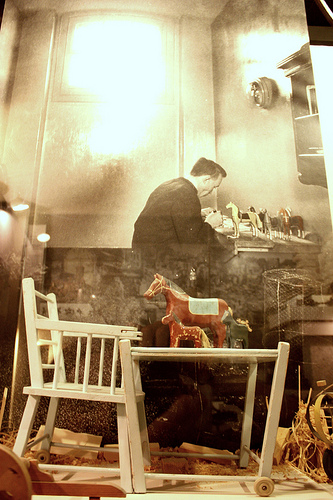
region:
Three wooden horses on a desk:
[143, 272, 249, 348]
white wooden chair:
[12, 278, 150, 493]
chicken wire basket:
[260, 268, 331, 363]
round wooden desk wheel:
[252, 476, 274, 496]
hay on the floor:
[0, 365, 332, 482]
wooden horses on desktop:
[225, 201, 303, 240]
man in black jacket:
[131, 157, 226, 263]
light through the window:
[51, 9, 176, 103]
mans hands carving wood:
[200, 206, 223, 229]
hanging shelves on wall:
[275, 42, 327, 189]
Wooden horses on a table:
[141, 262, 256, 368]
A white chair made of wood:
[24, 289, 133, 492]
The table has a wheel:
[174, 449, 302, 493]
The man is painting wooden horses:
[165, 146, 302, 240]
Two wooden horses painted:
[138, 270, 245, 346]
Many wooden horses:
[219, 192, 314, 239]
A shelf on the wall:
[274, 50, 327, 185]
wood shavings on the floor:
[156, 442, 244, 483]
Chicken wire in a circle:
[262, 263, 316, 346]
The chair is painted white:
[20, 302, 127, 406]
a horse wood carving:
[143, 274, 249, 347]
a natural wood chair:
[13, 277, 130, 492]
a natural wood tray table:
[120, 339, 289, 496]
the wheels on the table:
[253, 475, 274, 496]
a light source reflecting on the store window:
[0, 197, 29, 229]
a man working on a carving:
[132, 156, 223, 274]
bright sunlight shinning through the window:
[60, 12, 177, 104]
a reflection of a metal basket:
[261, 268, 322, 341]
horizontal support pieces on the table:
[143, 471, 260, 483]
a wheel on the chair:
[36, 448, 50, 463]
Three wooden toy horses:
[144, 270, 251, 345]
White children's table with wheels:
[113, 338, 288, 498]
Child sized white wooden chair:
[10, 276, 141, 492]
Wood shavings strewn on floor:
[260, 363, 331, 486]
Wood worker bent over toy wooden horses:
[132, 156, 234, 249]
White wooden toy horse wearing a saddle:
[224, 200, 260, 239]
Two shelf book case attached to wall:
[277, 42, 332, 194]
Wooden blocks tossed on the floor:
[30, 424, 236, 465]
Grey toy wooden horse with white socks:
[260, 207, 286, 240]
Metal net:
[261, 268, 325, 369]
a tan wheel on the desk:
[251, 474, 280, 499]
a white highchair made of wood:
[8, 271, 152, 497]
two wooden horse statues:
[142, 270, 246, 347]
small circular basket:
[262, 256, 325, 362]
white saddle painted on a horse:
[186, 291, 220, 319]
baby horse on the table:
[163, 313, 207, 346]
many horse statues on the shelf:
[223, 199, 305, 238]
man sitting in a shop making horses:
[131, 154, 317, 246]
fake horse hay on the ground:
[278, 402, 331, 483]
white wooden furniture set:
[13, 278, 293, 495]